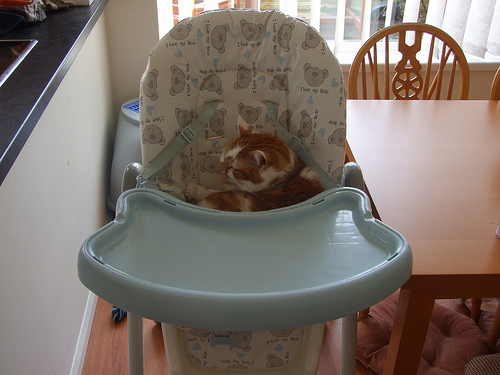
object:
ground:
[299, 158, 325, 180]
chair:
[347, 22, 471, 101]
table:
[337, 98, 498, 375]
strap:
[134, 97, 223, 182]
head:
[217, 115, 296, 191]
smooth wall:
[0, 13, 108, 375]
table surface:
[95, 192, 390, 296]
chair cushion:
[137, 10, 349, 375]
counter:
[0, 0, 109, 190]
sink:
[0, 39, 37, 89]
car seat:
[134, 7, 347, 374]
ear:
[236, 115, 251, 137]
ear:
[254, 149, 268, 168]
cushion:
[356, 292, 487, 375]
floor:
[77, 299, 499, 375]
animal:
[196, 113, 325, 212]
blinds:
[151, 0, 496, 64]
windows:
[154, 0, 498, 66]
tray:
[80, 187, 412, 296]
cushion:
[137, 9, 349, 375]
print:
[234, 63, 254, 91]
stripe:
[218, 147, 289, 192]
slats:
[338, 29, 498, 70]